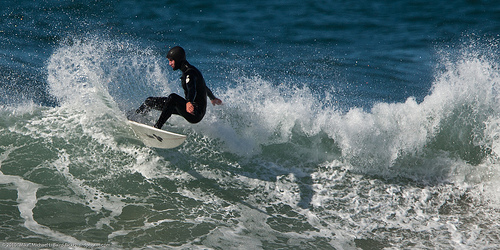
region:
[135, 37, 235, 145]
person wearing black wet suit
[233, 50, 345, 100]
wave splash water droplets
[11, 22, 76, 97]
wave splash water droplets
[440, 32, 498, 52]
wave splash water droplets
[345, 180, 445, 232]
foamy look in ocean water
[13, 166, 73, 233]
foamy look in ocean water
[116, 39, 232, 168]
person on surfboard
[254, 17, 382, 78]
ripples in ocean water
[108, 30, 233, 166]
person riding a surfboard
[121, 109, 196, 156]
white surfboard in water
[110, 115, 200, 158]
the surfboard is white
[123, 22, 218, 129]
wet suit is black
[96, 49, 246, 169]
wet suit is black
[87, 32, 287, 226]
wet suit is black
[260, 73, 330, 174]
part of a splash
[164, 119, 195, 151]
edge of a board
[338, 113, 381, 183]
part of a splash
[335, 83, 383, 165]
part of a splash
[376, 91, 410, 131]
part of a splash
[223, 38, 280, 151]
part of a splash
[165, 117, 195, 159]
edge of a board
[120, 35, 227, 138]
THE MAN IS WEARING A WET SUIT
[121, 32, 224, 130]
THE WET SUIT IS WET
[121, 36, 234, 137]
THE MAN IS IN A WET SUIT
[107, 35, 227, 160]
THE MAN IS ON THE SURFBOARD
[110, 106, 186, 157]
THE SURF BOARD IS WHITE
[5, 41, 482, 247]
THE WAVE IS BIG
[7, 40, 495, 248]
THE WAVE IS BREAKING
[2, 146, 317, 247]
THE FOAM IS WHITE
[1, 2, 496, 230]
THE OCEAN IS BLUE AND DEEP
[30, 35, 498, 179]
THE WAVE IS SPLASHING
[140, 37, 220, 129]
this is a man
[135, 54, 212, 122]
the man is sea surfing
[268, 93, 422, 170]
waves are on the sea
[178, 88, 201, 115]
the hand is behind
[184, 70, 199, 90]
the costume is black in color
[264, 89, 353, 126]
the water is splashy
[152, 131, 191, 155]
this is the board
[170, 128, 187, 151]
the front is sharp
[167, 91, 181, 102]
this is the knee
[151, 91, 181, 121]
the leg is bent